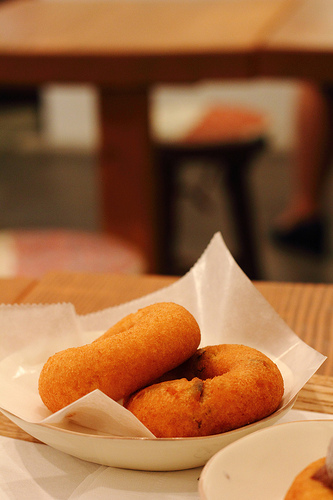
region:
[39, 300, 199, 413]
a donut stacked on a donut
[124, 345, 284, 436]
a donut under a donut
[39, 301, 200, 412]
cake donut laying at an angle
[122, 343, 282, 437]
cake donut laying on a piece of paper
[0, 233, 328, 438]
a piece of paper separating donuts from plate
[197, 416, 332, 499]
saucer with a golden edge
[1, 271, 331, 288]
the edge of a wood grain table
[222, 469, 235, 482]
a speck on a white saucer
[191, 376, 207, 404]
a dark spot on the cake donut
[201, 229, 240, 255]
the triangular tip of a piece of paper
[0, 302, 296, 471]
center dish has serving of two donuts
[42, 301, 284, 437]
donuts are plain cake without frosting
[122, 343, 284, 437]
donut on right is almost flat on dish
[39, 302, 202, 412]
donut on left is placed on top of other donut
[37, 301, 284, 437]
donuts are a warm golden color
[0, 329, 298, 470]
white saucer is accented with thin brown paing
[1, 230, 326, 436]
white wax paper is underneath donuts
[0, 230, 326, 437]
white wax paper is perforated at edges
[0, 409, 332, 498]
white wax paper underneath serving bowl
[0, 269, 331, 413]
table is made of light colored wood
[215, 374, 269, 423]
a brown donut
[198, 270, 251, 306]
tissue paper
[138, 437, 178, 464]
a bowl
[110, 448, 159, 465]
the bowl is white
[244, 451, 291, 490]
inside the bowl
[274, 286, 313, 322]
a table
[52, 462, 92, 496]
a shadow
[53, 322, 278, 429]
two donuts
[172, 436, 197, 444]
rim of the bowl is gold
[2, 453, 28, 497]
tissue paper on the table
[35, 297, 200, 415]
yellow and orange cake donut in shallow bowl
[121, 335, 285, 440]
yellow and orange cake donut in shallow white bowl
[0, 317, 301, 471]
shallow white bowl on table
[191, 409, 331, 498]
shallow white bowl on table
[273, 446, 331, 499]
donut in shallow white bowl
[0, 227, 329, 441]
thin white paper under doughnuts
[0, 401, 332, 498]
white napkins under bowls on table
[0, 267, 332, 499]
brown wooden table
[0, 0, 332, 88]
brown wooden table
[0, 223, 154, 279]
circular brown wooden stool next to table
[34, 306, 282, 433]
Two donuts in a bowl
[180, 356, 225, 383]
A hole in the donut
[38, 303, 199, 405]
The donut has no frosting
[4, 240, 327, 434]
White paper beneath the donuts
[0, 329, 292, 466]
A white bowl on the table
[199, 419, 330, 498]
A white bowl containing food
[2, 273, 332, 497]
A table beneath the bowls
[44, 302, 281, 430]
Two donuts above the table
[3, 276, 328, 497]
The table is made of wood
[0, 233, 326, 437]
The white sheet is in the bowl